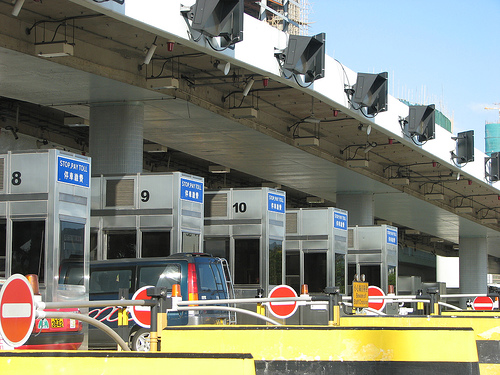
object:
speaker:
[177, 0, 245, 53]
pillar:
[86, 101, 146, 175]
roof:
[0, 0, 500, 259]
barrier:
[159, 323, 484, 374]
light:
[168, 282, 183, 298]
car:
[12, 306, 85, 350]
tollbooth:
[0, 147, 93, 355]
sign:
[263, 192, 286, 214]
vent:
[103, 177, 135, 208]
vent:
[200, 192, 229, 219]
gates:
[0, 272, 166, 352]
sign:
[55, 154, 92, 189]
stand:
[0, 147, 93, 351]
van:
[57, 252, 237, 354]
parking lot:
[0, 0, 499, 374]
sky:
[306, 0, 498, 158]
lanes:
[35, 284, 162, 355]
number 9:
[139, 189, 151, 203]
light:
[397, 102, 438, 148]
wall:
[270, 79, 499, 193]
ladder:
[214, 255, 238, 326]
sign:
[350, 280, 369, 309]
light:
[185, 261, 200, 315]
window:
[89, 265, 134, 293]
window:
[135, 264, 181, 291]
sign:
[177, 175, 204, 205]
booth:
[87, 170, 207, 263]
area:
[0, 1, 499, 231]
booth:
[283, 205, 350, 298]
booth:
[343, 224, 398, 300]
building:
[0, 0, 499, 312]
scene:
[0, 1, 499, 375]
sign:
[126, 284, 168, 330]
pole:
[167, 295, 312, 306]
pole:
[340, 294, 430, 300]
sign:
[266, 282, 298, 320]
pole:
[436, 292, 485, 299]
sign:
[354, 284, 387, 316]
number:
[231, 200, 248, 214]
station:
[203, 187, 288, 326]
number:
[9, 169, 22, 187]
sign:
[470, 292, 495, 313]